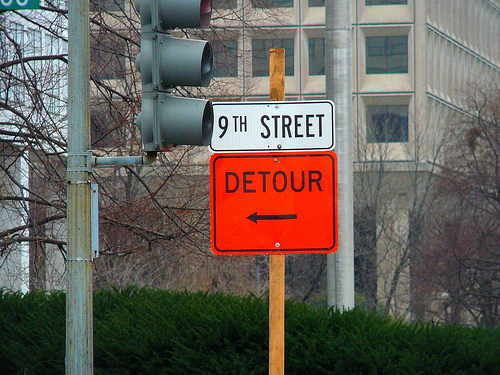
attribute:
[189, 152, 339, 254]
sign — red, traffic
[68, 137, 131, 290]
light — gray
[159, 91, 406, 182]
sign —  white street name 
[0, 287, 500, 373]
bushes — the background, green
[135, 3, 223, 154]
traffic light — traffic signal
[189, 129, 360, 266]
sign — steel , white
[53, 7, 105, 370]
steel poll — metal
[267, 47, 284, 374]
pole — wood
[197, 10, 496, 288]
building — the background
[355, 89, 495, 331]
trees — dead, leafless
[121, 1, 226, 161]
traffic lights — different colors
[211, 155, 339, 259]
traffic sign — red, detour sign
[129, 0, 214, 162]
traffic light — gray, illuminated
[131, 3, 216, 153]
light — red, green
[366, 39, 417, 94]
building — concrete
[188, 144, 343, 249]
detour sign — temporary, orange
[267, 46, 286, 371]
stick — wooden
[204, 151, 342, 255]
sign — square, street sign, red, red detour signal 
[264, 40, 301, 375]
pole — wood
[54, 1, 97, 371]
pole — rusty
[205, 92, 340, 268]
sign — street name